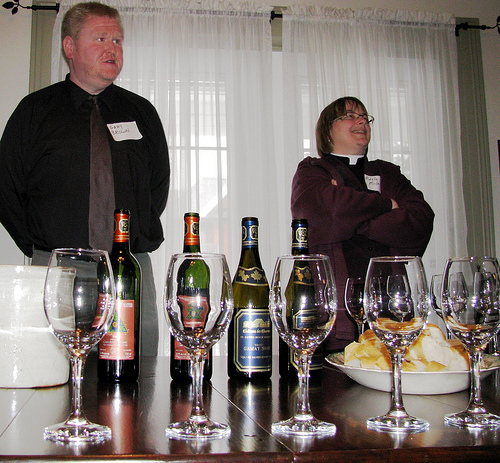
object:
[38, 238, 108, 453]
glass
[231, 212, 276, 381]
bottle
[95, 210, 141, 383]
bottles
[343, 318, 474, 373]
bread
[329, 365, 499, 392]
bowl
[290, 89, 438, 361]
woman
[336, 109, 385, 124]
glasses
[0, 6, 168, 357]
man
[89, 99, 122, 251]
tie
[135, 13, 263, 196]
curtains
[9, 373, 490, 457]
table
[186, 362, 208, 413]
handle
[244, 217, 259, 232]
top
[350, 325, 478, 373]
food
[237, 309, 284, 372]
sticker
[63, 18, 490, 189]
window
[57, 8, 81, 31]
hair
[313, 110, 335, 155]
hair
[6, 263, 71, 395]
canister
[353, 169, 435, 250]
arms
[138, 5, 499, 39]
rod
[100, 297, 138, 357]
label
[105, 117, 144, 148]
name tag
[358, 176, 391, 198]
name tag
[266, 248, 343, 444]
glass